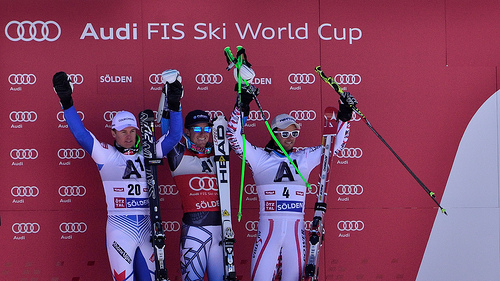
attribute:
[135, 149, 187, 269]
skis — white, black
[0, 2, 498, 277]
wall — red, white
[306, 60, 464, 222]
pole — yellow, black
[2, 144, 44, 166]
rings — linked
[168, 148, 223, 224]
top — red, grey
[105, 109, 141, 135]
hat — black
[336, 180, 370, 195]
rings — linked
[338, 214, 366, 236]
rings — linked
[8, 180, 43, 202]
rings — linked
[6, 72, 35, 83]
rings — linked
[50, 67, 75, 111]
glove — black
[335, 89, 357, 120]
glove — black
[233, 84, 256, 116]
glove — black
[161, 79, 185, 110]
glove — black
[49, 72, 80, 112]
gloves — black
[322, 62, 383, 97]
rings — linked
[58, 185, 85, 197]
rings — linked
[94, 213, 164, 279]
pants — red, white, blue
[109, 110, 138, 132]
cap — white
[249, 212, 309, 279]
pants — red, white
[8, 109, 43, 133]
rings — linked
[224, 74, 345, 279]
top — black, white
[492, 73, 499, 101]
tent — blue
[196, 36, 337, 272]
poles — green